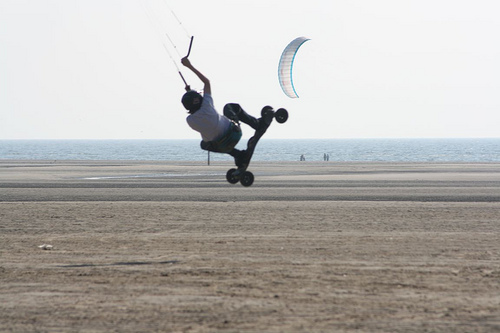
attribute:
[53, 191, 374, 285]
ground — covered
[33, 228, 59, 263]
rock — grey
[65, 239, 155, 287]
shadow — cast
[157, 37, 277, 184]
person — airborn, holding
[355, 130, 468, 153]
water — standing, calm, blue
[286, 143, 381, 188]
people — standing, grouped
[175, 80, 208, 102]
helmet — black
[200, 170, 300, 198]
wheels — black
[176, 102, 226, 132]
shirt — white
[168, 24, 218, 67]
pole — wooden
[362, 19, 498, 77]
sky — white, gray, grey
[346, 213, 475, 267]
sand — brown, tan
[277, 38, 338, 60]
object — flying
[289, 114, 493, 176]
ocean — here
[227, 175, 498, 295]
beach — sand, here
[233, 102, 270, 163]
skateboard — under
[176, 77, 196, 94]
hand — black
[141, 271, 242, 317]
terrain — rough